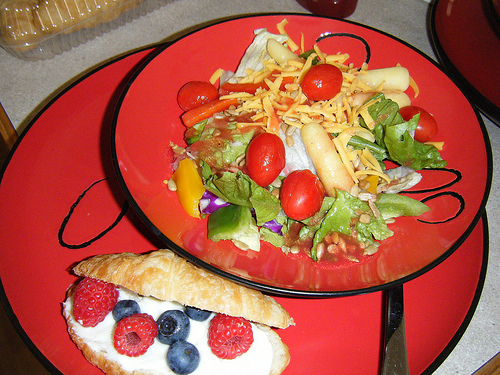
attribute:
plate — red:
[109, 14, 487, 297]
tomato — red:
[280, 168, 325, 220]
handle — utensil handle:
[377, 289, 407, 368]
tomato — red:
[173, 75, 225, 122]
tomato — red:
[401, 103, 435, 144]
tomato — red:
[281, 56, 366, 100]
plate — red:
[1, 37, 492, 374]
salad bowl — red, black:
[119, 7, 494, 287]